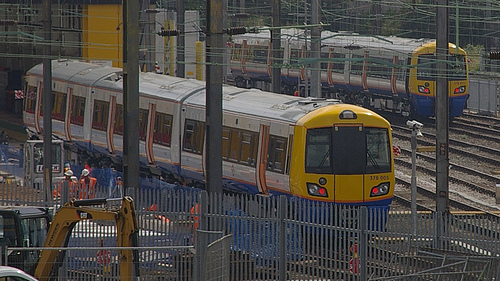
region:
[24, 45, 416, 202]
This is a commuter train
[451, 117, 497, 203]
These are train tracks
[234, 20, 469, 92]
Another train is in the background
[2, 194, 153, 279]
This is an excavator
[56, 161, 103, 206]
The two men are wearing orange vests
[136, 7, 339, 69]
Electric wires are above the train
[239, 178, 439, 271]
A fence is near the train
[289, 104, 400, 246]
The train's front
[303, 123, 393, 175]
This is the trains wind shield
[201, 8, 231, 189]
A steel post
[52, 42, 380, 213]
train is grey and yellow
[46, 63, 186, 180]
train has grey cars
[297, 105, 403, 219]
train has yellow front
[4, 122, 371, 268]
blue fence near train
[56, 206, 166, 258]
yellow construction equipment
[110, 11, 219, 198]
grey bars next to train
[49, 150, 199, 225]
people wearing orange near train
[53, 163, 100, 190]
people wear hard hats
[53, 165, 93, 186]
hard hats are white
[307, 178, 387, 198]
red headlights on train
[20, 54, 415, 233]
a white yellow and blue train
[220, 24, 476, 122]
a white yellow and blue train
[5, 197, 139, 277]
a yellow excavator vehicle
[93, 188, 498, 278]
long grey metal fence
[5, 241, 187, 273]
portable grey metal fencing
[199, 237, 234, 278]
portable grey metal fencing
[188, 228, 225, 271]
portable grey metal fencing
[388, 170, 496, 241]
a set of train tracks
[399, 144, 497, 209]
a set of train tracks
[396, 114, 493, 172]
a set of train tracks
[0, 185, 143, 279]
A yellow caterpillar lift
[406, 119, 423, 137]
Cameras on a pole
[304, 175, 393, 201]
Headlights on a train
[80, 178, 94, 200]
Orange work vests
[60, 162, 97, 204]
People working construction at the trainyard.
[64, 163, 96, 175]
White hard hats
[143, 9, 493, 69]
Power lines hanging overhead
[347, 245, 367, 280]
A red stop sign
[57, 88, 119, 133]
Windows on the train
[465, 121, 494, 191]
Tracks on the ground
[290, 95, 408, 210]
front of train is yellow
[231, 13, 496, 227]
two trains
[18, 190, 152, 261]
bulldozer is yellow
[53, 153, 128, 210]
workers wearing safety vests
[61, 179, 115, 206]
safety vest are orange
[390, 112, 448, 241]
camera on the tracks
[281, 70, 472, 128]
bottom of train is blue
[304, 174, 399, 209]
lights on the front of train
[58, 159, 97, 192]
workers wearing white helmets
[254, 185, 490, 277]
metal fence along train tracks